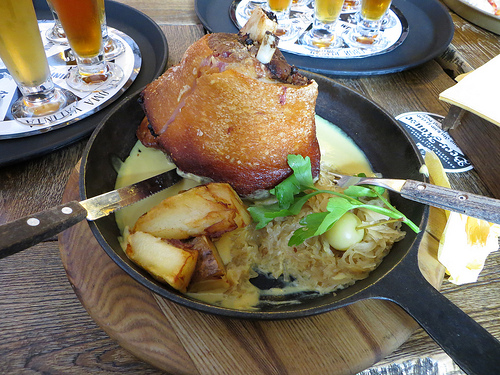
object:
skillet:
[76, 74, 500, 371]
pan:
[76, 62, 498, 374]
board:
[43, 68, 499, 373]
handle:
[381, 273, 497, 375]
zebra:
[0, 262, 61, 356]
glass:
[48, 0, 122, 92]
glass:
[0, 0, 80, 124]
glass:
[303, 0, 350, 49]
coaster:
[395, 112, 475, 173]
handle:
[1, 202, 86, 260]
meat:
[139, 34, 324, 192]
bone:
[235, 7, 284, 64]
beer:
[0, 0, 106, 87]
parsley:
[245, 156, 419, 248]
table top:
[0, 0, 499, 373]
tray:
[193, 0, 454, 77]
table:
[0, 1, 497, 372]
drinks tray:
[231, 2, 405, 58]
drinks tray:
[0, 14, 143, 135]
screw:
[455, 193, 470, 205]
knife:
[0, 164, 184, 255]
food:
[110, 19, 400, 311]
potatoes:
[119, 184, 244, 294]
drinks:
[0, 0, 115, 118]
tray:
[1, 1, 169, 171]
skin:
[195, 76, 259, 131]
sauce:
[123, 146, 155, 183]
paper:
[45, 42, 71, 82]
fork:
[314, 162, 498, 228]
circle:
[24, 216, 42, 227]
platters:
[0, 4, 166, 164]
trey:
[9, 80, 80, 123]